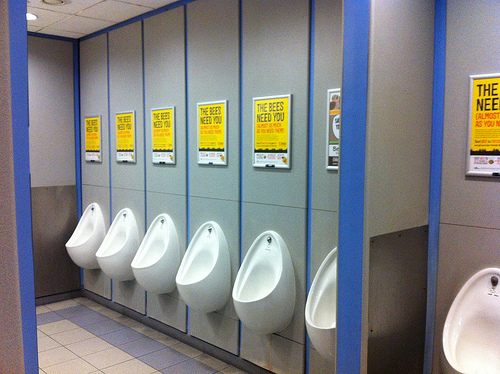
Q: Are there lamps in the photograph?
A: No, there are no lamps.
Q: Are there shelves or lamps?
A: No, there are no lamps or shelves.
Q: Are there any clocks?
A: No, there are no clocks.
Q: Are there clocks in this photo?
A: No, there are no clocks.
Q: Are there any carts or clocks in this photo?
A: No, there are no clocks or carts.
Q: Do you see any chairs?
A: No, there are no chairs.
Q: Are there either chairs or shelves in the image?
A: No, there are no chairs or shelves.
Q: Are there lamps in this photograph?
A: No, there are no lamps.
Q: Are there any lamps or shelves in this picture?
A: No, there are no lamps or shelves.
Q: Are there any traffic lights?
A: No, there are no traffic lights.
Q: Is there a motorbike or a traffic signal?
A: No, there are no traffic lights or motorcycles.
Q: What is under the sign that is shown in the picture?
A: The urinal is under the sign.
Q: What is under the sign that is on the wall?
A: The urinal is under the sign.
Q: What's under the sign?
A: The urinal is under the sign.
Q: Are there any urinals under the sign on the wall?
A: Yes, there is a urinal under the sign.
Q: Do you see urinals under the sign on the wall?
A: Yes, there is a urinal under the sign.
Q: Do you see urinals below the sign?
A: Yes, there is a urinal below the sign.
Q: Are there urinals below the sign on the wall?
A: Yes, there is a urinal below the sign.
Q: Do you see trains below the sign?
A: No, there is a urinal below the sign.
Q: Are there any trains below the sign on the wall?
A: No, there is a urinal below the sign.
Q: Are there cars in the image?
A: No, there are no cars.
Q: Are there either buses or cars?
A: No, there are no cars or buses.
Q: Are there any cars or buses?
A: No, there are no cars or buses.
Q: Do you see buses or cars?
A: No, there are no cars or buses.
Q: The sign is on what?
A: The sign is on the wall.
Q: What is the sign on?
A: The sign is on the wall.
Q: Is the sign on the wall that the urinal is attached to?
A: Yes, the sign is on the wall.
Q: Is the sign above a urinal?
A: Yes, the sign is above a urinal.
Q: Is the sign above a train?
A: No, the sign is above a urinal.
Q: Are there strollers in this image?
A: No, there are no strollers.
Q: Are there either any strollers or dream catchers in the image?
A: No, there are no strollers or dream catchers.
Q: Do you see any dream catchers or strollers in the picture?
A: No, there are no strollers or dream catchers.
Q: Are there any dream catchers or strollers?
A: No, there are no strollers or dream catchers.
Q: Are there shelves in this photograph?
A: No, there are no shelves.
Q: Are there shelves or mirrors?
A: No, there are no shelves or mirrors.